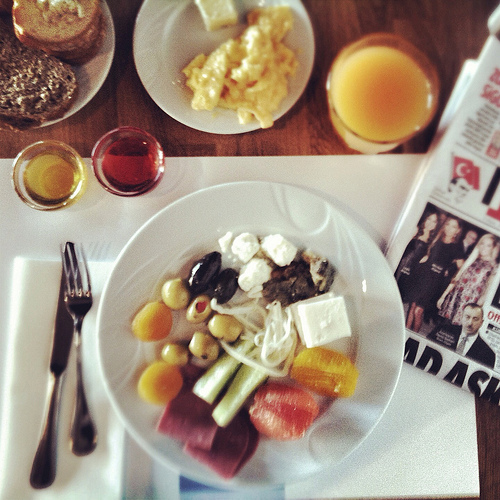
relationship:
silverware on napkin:
[21, 236, 118, 492] [3, 253, 136, 498]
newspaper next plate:
[367, 30, 497, 410] [59, 169, 424, 496]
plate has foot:
[83, 178, 420, 498] [123, 225, 369, 485]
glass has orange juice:
[316, 22, 446, 157] [324, 32, 437, 154]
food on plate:
[131, 232, 353, 475] [83, 178, 420, 498]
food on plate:
[131, 232, 353, 475] [59, 169, 424, 496]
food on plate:
[131, 232, 353, 475] [97, 182, 485, 494]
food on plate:
[131, 232, 353, 475] [75, 178, 439, 479]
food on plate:
[223, 268, 342, 355] [127, 225, 368, 480]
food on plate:
[223, 268, 342, 355] [72, 183, 407, 458]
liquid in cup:
[17, 153, 83, 205] [5, 134, 92, 214]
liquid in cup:
[103, 142, 153, 184] [90, 125, 167, 195]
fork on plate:
[59, 243, 97, 457] [83, 178, 420, 498]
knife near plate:
[29, 243, 79, 491] [104, 179, 411, 490]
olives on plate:
[165, 252, 245, 344] [97, 193, 398, 490]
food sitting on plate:
[182, 0, 302, 130] [126, 30, 359, 134]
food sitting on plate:
[131, 232, 353, 475] [83, 178, 420, 498]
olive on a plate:
[162, 279, 189, 310] [83, 178, 420, 498]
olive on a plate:
[187, 290, 210, 323] [83, 178, 420, 498]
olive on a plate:
[209, 312, 241, 342] [83, 178, 420, 498]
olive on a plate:
[184, 330, 219, 360] [83, 178, 420, 498]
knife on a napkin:
[29, 243, 79, 491] [1, 256, 115, 498]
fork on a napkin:
[58, 243, 96, 455] [1, 256, 115, 498]